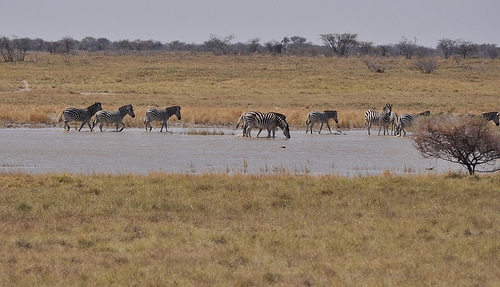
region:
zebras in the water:
[57, 93, 428, 140]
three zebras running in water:
[55, 94, 185, 138]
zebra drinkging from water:
[243, 108, 292, 136]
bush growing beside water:
[417, 115, 496, 173]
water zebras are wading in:
[3, 113, 486, 176]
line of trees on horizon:
[10, 31, 490, 60]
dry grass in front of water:
[20, 175, 497, 276]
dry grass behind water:
[5, 53, 480, 115]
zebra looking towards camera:
[364, 100, 391, 133]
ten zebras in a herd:
[52, 96, 498, 151]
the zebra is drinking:
[228, 106, 294, 152]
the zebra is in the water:
[231, 100, 294, 164]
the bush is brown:
[399, 116, 494, 170]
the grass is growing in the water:
[176, 129, 229, 149]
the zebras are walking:
[50, 90, 188, 148]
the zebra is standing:
[357, 103, 399, 135]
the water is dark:
[142, 146, 249, 172]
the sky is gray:
[209, 3, 321, 33]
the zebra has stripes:
[253, 115, 268, 123]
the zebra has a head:
[167, 104, 190, 121]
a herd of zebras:
[12, 36, 492, 196]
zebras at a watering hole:
[54, 86, 457, 177]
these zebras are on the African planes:
[10, 51, 474, 224]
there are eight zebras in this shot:
[44, 83, 446, 145]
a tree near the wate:
[420, 101, 497, 181]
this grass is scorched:
[18, 173, 444, 270]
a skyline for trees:
[3, 23, 475, 66]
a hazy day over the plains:
[24, 6, 464, 28]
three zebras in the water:
[40, 85, 198, 132]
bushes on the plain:
[347, 53, 450, 87]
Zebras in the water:
[60, 97, 431, 132]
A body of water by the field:
[1, 116, 496, 172]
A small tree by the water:
[415, 115, 495, 170]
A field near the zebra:
[0, 170, 495, 280]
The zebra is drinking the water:
[235, 111, 290, 136]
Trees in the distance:
[6, 35, 496, 60]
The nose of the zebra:
[177, 115, 182, 118]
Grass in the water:
[184, 130, 234, 133]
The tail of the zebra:
[233, 113, 244, 128]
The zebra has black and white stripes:
[248, 110, 277, 126]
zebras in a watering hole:
[41, 87, 485, 153]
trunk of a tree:
[460, 158, 481, 176]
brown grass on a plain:
[25, 180, 480, 258]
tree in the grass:
[405, 103, 496, 174]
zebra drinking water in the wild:
[232, 97, 292, 148]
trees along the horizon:
[25, 23, 430, 75]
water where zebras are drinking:
[33, 138, 199, 160]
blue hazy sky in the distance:
[35, 5, 457, 30]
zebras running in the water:
[55, 90, 140, 133]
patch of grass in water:
[182, 122, 227, 137]